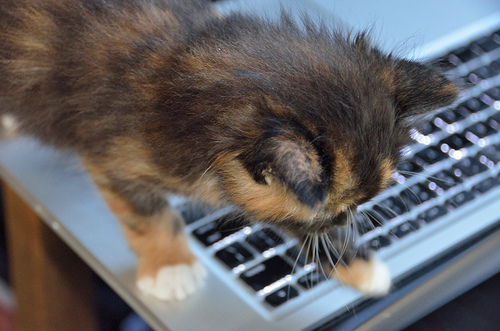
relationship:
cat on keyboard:
[0, 0, 456, 303] [172, 24, 498, 317]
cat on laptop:
[0, 0, 456, 303] [2, 0, 498, 327]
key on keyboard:
[215, 239, 255, 274] [172, 24, 498, 317]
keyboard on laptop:
[172, 24, 498, 317] [2, 0, 498, 327]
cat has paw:
[0, 0, 456, 303] [128, 259, 208, 301]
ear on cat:
[389, 54, 462, 128] [0, 0, 456, 303]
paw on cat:
[128, 259, 208, 301] [0, 0, 456, 303]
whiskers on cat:
[282, 231, 352, 299] [0, 0, 456, 303]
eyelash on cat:
[333, 207, 392, 259] [0, 0, 456, 303]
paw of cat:
[128, 259, 208, 301] [0, 0, 456, 303]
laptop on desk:
[2, 0, 498, 327] [322, 228, 499, 331]